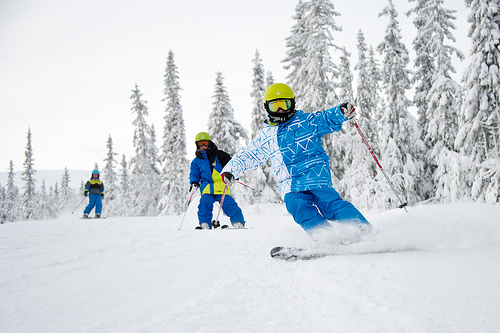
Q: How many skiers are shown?
A: Three.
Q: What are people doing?
A: Skiing.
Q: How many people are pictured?
A: Three.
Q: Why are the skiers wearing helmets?
A: Protection.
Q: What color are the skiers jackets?
A: Blue, yellow, black, and white.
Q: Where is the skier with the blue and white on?
A: Front.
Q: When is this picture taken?
A: Winter.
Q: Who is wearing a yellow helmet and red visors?
A: Middle skier.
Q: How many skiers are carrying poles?
A: Allt three.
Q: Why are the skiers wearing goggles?
A: Protection.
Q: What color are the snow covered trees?
A: White.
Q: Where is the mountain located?
A: Distance.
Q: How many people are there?
A: Three.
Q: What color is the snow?
A: White.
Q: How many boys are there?
A: Three.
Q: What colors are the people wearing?
A: Blue and yellow.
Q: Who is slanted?
A: The boy.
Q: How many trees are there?
A: More than ten.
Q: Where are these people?
A: On a ski trail.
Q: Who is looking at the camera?
A: The closest skier.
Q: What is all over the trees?
A: Snow.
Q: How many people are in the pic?
A: Three.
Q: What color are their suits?
A: White, blue, and yellow.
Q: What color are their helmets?
A: Lime green and blue.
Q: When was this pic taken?
A: During the day.